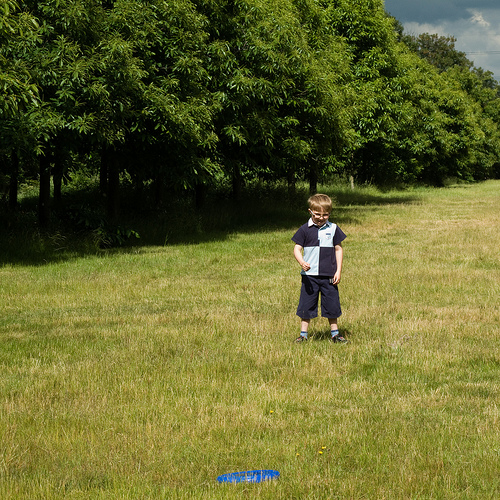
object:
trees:
[1, 0, 499, 247]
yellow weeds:
[268, 405, 276, 415]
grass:
[5, 386, 80, 493]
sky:
[403, 1, 499, 80]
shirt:
[290, 219, 349, 278]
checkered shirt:
[290, 218, 347, 275]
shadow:
[307, 327, 352, 342]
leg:
[319, 277, 342, 333]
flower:
[295, 450, 304, 462]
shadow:
[3, 183, 421, 267]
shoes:
[330, 329, 346, 344]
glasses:
[309, 210, 332, 219]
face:
[312, 212, 327, 226]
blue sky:
[390, 0, 500, 47]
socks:
[330, 330, 340, 337]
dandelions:
[262, 404, 327, 464]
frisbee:
[214, 468, 279, 484]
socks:
[299, 330, 307, 338]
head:
[307, 193, 332, 226]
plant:
[93, 220, 140, 254]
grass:
[412, 187, 497, 277]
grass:
[119, 243, 232, 284]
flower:
[313, 450, 324, 456]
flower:
[318, 442, 328, 451]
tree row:
[1, 0, 498, 257]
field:
[0, 171, 497, 497]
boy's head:
[307, 194, 332, 227]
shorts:
[297, 277, 340, 318]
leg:
[296, 276, 319, 335]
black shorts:
[294, 274, 341, 321]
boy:
[289, 192, 350, 343]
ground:
[0, 179, 499, 500]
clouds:
[464, 40, 484, 54]